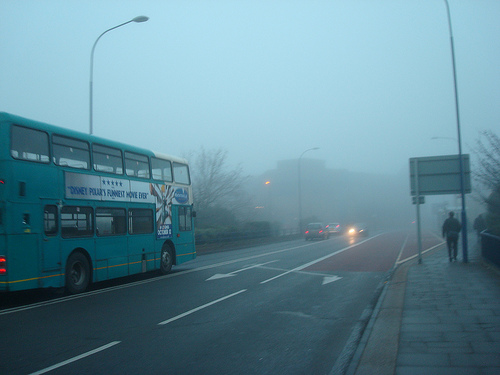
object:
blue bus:
[0, 108, 199, 298]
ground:
[295, 265, 498, 373]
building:
[191, 162, 314, 220]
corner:
[275, 190, 315, 204]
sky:
[204, 9, 394, 111]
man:
[440, 211, 463, 262]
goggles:
[447, 211, 455, 214]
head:
[446, 210, 455, 218]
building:
[269, 160, 403, 227]